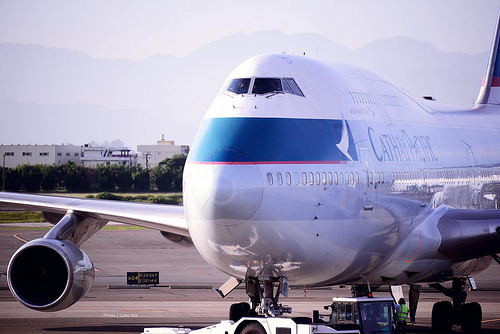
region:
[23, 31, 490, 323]
a passenger jumbo jet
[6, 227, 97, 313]
jet engine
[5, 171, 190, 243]
a wing of the aircraft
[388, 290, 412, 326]
ground crew in a bright yellow vest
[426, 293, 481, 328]
wheels of the aircraft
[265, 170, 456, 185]
passenger windows on the aircraft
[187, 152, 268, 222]
nose of the aircraft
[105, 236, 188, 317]
the airport tarmac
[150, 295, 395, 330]
vehicle used for loading passenger's luggage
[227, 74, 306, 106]
the aircraft cockpit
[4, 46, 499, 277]
this is a plane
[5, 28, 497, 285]
the plane is big in size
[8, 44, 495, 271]
the plane is white in color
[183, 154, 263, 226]
the plane has streamlined head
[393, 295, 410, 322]
this is a man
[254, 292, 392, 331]
this is a truck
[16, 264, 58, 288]
the propeller is dark in it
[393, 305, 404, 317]
he is wearing a reflector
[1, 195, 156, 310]
the wing is big in siz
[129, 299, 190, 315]
the road is clean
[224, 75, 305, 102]
the windshield of the plane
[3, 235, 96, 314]
the engine of a plane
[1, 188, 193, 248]
the wing of a plane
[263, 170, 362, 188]
a row of plane windows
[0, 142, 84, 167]
a white building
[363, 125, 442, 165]
blue writing on the plane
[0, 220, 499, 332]
a gray cement runway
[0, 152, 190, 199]
a row of small green trees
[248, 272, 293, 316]
the landing gear of a plane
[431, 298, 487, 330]
the wheels of a plane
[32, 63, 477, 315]
large white airplane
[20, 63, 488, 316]
airplane on runway at airport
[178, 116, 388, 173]
blue and red stripe on front of airplane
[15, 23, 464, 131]
foggy mountains in the background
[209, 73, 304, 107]
windshield of airplane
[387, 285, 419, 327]
airport working in green safety vest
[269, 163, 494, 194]
passenger windows on airplane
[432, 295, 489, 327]
black wheels on airplane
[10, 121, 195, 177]
white buildings in the the background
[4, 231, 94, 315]
airplane propellers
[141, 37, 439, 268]
Large aircraft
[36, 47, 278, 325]
Large aircraft on the flight line.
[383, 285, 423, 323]
Airport personnel on the ground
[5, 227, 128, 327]
Jet engine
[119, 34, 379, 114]
Mountains behind the plane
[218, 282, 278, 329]
Front landing gear on the aircraft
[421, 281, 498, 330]
Rear landing gear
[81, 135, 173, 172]
Buildings behind the plane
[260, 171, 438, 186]
Windows on the side of the aircraft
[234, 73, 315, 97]
Cockpit on the aircraft